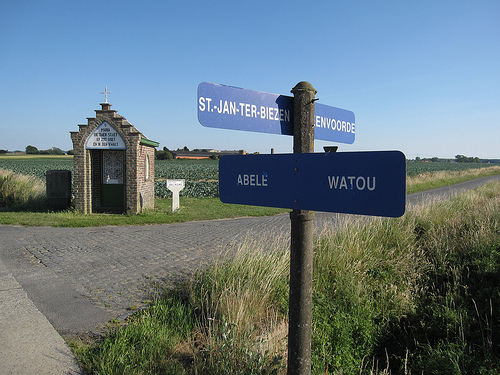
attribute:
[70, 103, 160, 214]
building — brown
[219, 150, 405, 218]
sign — blue, rectangular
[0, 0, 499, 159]
sky — blue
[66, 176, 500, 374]
grass — tall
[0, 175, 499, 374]
road — empty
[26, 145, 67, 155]
tree — here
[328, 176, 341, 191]
letter — white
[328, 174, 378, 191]
print — white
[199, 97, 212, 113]
print — white